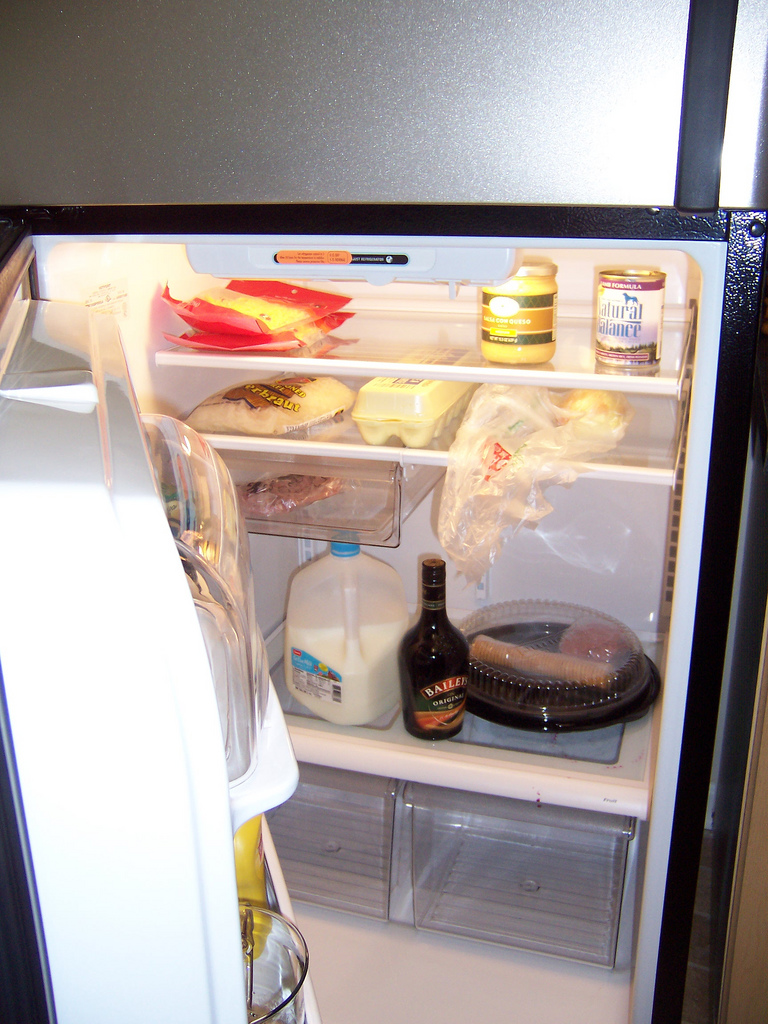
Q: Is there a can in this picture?
A: Yes, there is a can.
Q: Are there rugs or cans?
A: Yes, there is a can.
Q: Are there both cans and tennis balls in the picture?
A: No, there is a can but no tennis balls.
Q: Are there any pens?
A: No, there are no pens.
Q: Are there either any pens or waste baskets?
A: No, there are no pens or waste baskets.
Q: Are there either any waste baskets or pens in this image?
A: No, there are no pens or waste baskets.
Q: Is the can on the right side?
A: Yes, the can is on the right of the image.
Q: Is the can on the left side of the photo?
A: No, the can is on the right of the image.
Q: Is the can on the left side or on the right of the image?
A: The can is on the right of the image.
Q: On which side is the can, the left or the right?
A: The can is on the right of the image.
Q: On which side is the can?
A: The can is on the right of the image.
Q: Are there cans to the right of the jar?
A: Yes, there is a can to the right of the jar.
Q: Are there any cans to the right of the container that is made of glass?
A: Yes, there is a can to the right of the jar.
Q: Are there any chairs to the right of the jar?
A: No, there is a can to the right of the jar.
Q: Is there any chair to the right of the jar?
A: No, there is a can to the right of the jar.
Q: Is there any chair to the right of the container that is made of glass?
A: No, there is a can to the right of the jar.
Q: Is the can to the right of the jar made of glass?
A: Yes, the can is to the right of the jar.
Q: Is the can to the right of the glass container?
A: Yes, the can is to the right of the jar.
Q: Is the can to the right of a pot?
A: No, the can is to the right of the jar.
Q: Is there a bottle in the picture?
A: Yes, there is a bottle.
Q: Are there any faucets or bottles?
A: Yes, there is a bottle.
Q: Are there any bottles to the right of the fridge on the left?
A: Yes, there is a bottle to the right of the freezer.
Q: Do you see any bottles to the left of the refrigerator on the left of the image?
A: No, the bottle is to the right of the freezer.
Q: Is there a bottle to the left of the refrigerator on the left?
A: No, the bottle is to the right of the freezer.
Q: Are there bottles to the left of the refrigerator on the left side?
A: No, the bottle is to the right of the freezer.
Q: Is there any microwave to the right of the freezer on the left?
A: No, there is a bottle to the right of the freezer.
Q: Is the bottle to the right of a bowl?
A: No, the bottle is to the right of the fridge.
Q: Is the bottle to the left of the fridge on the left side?
A: No, the bottle is to the right of the fridge.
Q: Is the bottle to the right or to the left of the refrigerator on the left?
A: The bottle is to the right of the fridge.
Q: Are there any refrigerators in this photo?
A: Yes, there is a refrigerator.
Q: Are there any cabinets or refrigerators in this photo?
A: Yes, there is a refrigerator.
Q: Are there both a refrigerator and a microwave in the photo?
A: No, there is a refrigerator but no microwaves.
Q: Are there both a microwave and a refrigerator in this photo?
A: No, there is a refrigerator but no microwaves.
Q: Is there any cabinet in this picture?
A: No, there are no cabinets.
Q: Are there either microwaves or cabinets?
A: No, there are no cabinets or microwaves.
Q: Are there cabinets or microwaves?
A: No, there are no cabinets or microwaves.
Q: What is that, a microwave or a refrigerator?
A: That is a refrigerator.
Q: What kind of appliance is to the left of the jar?
A: The appliance is a refrigerator.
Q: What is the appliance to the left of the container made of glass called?
A: The appliance is a refrigerator.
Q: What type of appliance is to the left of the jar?
A: The appliance is a refrigerator.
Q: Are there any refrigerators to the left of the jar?
A: Yes, there is a refrigerator to the left of the jar.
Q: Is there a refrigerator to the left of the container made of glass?
A: Yes, there is a refrigerator to the left of the jar.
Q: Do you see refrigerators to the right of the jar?
A: No, the refrigerator is to the left of the jar.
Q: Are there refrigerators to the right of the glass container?
A: No, the refrigerator is to the left of the jar.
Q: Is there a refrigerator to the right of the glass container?
A: No, the refrigerator is to the left of the jar.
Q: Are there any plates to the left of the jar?
A: No, there is a refrigerator to the left of the jar.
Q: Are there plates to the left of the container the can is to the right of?
A: No, there is a refrigerator to the left of the jar.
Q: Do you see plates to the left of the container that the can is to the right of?
A: No, there is a refrigerator to the left of the jar.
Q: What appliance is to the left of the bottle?
A: The appliance is a refrigerator.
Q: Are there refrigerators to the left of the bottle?
A: Yes, there is a refrigerator to the left of the bottle.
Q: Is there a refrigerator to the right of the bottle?
A: No, the refrigerator is to the left of the bottle.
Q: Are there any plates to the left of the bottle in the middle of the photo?
A: No, there is a refrigerator to the left of the bottle.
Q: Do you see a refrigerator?
A: Yes, there is a refrigerator.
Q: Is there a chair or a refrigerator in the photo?
A: Yes, there is a refrigerator.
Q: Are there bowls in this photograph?
A: No, there are no bowls.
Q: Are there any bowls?
A: No, there are no bowls.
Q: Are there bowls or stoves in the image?
A: No, there are no bowls or stoves.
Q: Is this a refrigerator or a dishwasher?
A: This is a refrigerator.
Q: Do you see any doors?
A: Yes, there is a door.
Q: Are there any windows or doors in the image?
A: Yes, there is a door.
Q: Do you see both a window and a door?
A: No, there is a door but no windows.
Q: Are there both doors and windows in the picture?
A: No, there is a door but no windows.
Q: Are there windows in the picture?
A: No, there are no windows.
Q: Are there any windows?
A: No, there are no windows.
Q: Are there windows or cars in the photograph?
A: No, there are no windows or cars.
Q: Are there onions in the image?
A: Yes, there is an onion.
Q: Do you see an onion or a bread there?
A: Yes, there is an onion.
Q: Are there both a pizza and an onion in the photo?
A: No, there is an onion but no pizzas.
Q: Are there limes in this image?
A: No, there are no limes.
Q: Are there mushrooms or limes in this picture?
A: No, there are no limes or mushrooms.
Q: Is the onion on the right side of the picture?
A: Yes, the onion is on the right of the image.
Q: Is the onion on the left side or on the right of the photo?
A: The onion is on the right of the image.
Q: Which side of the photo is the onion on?
A: The onion is on the right of the image.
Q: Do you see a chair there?
A: No, there are no chairs.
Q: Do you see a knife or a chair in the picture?
A: No, there are no chairs or knives.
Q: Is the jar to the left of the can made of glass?
A: Yes, the jar is made of glass.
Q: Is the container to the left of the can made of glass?
A: Yes, the jar is made of glass.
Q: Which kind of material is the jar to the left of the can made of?
A: The jar is made of glass.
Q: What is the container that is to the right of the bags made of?
A: The jar is made of glass.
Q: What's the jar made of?
A: The jar is made of glass.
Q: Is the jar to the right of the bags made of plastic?
A: No, the jar is made of glass.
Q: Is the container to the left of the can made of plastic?
A: No, the jar is made of glass.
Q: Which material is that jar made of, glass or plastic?
A: The jar is made of glass.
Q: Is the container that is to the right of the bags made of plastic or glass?
A: The jar is made of glass.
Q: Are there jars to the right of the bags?
A: Yes, there is a jar to the right of the bags.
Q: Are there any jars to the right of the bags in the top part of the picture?
A: Yes, there is a jar to the right of the bags.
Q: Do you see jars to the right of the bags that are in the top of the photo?
A: Yes, there is a jar to the right of the bags.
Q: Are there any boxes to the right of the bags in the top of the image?
A: No, there is a jar to the right of the bags.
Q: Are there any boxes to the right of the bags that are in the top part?
A: No, there is a jar to the right of the bags.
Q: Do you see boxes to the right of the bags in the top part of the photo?
A: No, there is a jar to the right of the bags.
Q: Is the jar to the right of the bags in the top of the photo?
A: Yes, the jar is to the right of the bags.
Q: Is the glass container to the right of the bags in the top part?
A: Yes, the jar is to the right of the bags.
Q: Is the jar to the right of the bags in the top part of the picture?
A: Yes, the jar is to the right of the bags.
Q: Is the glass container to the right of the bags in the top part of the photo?
A: Yes, the jar is to the right of the bags.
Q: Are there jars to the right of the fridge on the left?
A: Yes, there is a jar to the right of the freezer.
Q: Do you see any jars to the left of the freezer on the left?
A: No, the jar is to the right of the freezer.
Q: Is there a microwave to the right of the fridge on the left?
A: No, there is a jar to the right of the freezer.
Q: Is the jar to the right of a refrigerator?
A: Yes, the jar is to the right of a refrigerator.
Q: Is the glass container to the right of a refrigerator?
A: Yes, the jar is to the right of a refrigerator.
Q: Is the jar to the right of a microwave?
A: No, the jar is to the right of a refrigerator.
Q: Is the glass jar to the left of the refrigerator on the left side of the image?
A: No, the jar is to the right of the freezer.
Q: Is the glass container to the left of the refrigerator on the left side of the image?
A: No, the jar is to the right of the freezer.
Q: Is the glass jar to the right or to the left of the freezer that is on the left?
A: The jar is to the right of the freezer.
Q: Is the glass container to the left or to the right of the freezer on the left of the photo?
A: The jar is to the right of the freezer.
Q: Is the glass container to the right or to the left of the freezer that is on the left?
A: The jar is to the right of the freezer.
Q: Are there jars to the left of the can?
A: Yes, there is a jar to the left of the can.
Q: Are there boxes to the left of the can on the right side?
A: No, there is a jar to the left of the can.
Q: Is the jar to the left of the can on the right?
A: Yes, the jar is to the left of the can.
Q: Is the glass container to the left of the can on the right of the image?
A: Yes, the jar is to the left of the can.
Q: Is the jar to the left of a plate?
A: No, the jar is to the left of the can.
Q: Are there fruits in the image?
A: No, there are no fruits.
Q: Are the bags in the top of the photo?
A: Yes, the bags are in the top of the image.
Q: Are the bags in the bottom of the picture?
A: No, the bags are in the top of the image.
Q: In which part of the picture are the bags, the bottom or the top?
A: The bags are in the top of the image.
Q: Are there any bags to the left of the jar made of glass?
A: Yes, there are bags to the left of the jar.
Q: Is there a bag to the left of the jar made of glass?
A: Yes, there are bags to the left of the jar.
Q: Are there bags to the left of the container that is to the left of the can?
A: Yes, there are bags to the left of the jar.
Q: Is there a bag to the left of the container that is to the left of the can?
A: Yes, there are bags to the left of the jar.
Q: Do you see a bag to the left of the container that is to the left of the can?
A: Yes, there are bags to the left of the jar.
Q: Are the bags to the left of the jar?
A: Yes, the bags are to the left of the jar.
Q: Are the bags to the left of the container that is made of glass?
A: Yes, the bags are to the left of the jar.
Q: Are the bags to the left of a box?
A: No, the bags are to the left of the jar.